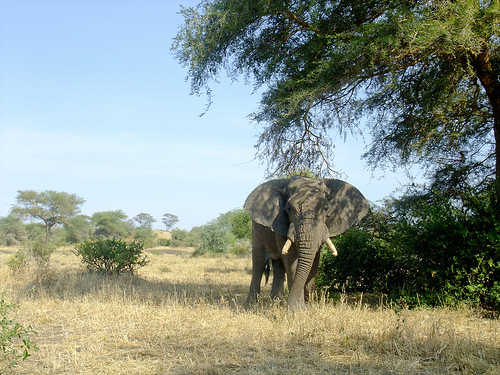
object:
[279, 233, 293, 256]
tusk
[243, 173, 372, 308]
elephant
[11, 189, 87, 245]
tree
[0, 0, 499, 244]
sky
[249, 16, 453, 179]
branches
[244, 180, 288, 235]
ear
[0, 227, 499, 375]
grass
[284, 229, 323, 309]
trunk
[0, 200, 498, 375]
ground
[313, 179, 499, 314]
bush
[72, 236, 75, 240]
leaves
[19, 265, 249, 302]
shadow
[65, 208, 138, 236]
hill